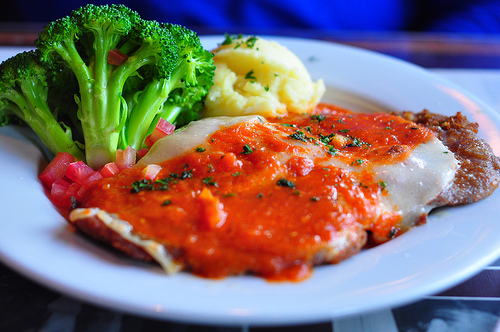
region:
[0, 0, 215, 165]
green colored broccoli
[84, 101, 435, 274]
a red tomato based sauce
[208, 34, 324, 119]
a mound of yellowish mashed potatoes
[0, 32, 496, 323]
a round white colored plate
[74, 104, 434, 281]
meat covered with a red sauce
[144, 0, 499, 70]
a person wearing blue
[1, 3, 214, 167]
green broccoli steamed on plate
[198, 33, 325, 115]
white mashed potatoes on plate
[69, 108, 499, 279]
pasta and sauce on plate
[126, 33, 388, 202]
green sprinkled seasoning on food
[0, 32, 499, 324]
white circular plate with food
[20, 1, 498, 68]
person is wearing blue shirt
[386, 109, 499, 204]
red meat sauce on plate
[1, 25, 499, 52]
wood edge on table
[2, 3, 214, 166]
bunch of cooked broccoli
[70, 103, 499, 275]
cheese and sauce on veal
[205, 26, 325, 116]
mashed potato with sprinkled parsley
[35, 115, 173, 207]
chopped red radish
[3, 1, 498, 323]
food on a white plate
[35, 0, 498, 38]
person wearing blue shirt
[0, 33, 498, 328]
round white ceramic plate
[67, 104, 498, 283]
veal parmesan on a plate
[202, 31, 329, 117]
mashed potatoes on a plate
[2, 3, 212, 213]
broccoli next to chopped radish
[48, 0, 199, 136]
Broccoli is on the plate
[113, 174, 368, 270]
A sort of dressing on the food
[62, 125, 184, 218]
Some slices of tomatos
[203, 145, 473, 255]
A sort of meat on the plate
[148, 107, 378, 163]
The food is all touching each other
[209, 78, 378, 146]
Mashed potatoes are on the plate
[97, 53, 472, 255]
A lot of good food on the plate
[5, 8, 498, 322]
round white plate holding a dinner meal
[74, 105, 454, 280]
bits of green herb sprinkled over tomato sauce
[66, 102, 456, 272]
melted white cheese under tomato sauce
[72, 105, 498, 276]
sauce and cheese over fried cutlet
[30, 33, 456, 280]
food on the plate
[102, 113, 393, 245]
seasoning on the food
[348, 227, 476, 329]
edge of the plate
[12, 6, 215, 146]
green food on plate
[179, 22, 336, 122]
white food on plate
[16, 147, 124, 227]
red food on the plate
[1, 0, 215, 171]
agreen broccoli head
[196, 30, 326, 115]
a small serving of mashed potatoes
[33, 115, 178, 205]
finely diced tomatoes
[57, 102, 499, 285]
chicken breast with sauce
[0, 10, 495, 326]
a plate of food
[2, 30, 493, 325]
white ceramic plate with food on it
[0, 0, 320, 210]
green red and white vegetables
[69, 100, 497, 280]
a piece opf meat with red sauce on it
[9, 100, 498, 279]
an entree coverd in sauce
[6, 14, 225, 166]
green colored broccoli on plate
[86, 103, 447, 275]
red pasta sauce on plate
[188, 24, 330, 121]
yellow mashed potatoes on plate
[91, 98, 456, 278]
piece of chicken on plate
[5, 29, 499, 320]
white colored plate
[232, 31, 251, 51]
green onions on mashed potatoes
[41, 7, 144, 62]
green broccoli head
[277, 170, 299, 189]
chives on the red sauce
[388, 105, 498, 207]
brown piece of meat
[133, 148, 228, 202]
green toppings on the food